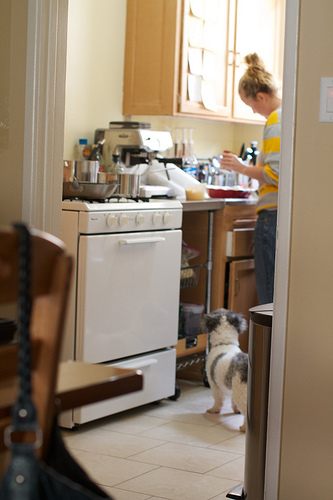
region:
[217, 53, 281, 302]
woman standing in the kitchen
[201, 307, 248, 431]
dog waiting for his food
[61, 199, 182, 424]
white stove in the corner of the kitchen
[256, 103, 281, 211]
yellow and gray top woman is wearing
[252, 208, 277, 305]
black pants woman is wearing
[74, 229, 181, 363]
front door of the white stove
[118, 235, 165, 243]
white stove door handle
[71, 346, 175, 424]
bottom drawer of the white stove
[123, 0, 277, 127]
wood cabinets on the sink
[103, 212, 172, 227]
knobs on the white stove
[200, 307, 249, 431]
A short haired white and grey dog.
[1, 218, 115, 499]
A black purse hanging on a chair.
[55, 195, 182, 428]
A white stove with black burners.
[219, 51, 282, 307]
A blonde woman in a yellow and grey shirt.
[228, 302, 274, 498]
A black and grey trashcan.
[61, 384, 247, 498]
A white tiled floor under and around a dog.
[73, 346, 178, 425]
Bottom white drawer on a stove.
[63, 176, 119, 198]
A silver frying pan on the front of the stove.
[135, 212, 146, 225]
The middle most white knob of a stove.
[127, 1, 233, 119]
Brown cabinet with sticky notes all over it.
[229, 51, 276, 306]
Woman wearing a striped shirt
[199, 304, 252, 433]
Dog standing on floor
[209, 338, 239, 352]
Collar around dog's neck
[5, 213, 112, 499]
Purse hanging on chair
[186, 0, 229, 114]
Paper hanging on cabinets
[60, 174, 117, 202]
Pan on the stove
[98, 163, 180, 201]
Pot on the stove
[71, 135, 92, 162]
Bottle next to stove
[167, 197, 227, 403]
Rack next to stove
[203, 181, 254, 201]
Platter on the counter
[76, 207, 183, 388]
that is an electric cooker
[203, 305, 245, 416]
that is a dog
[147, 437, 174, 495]
that is the kitchen floor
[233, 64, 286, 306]
that is a lady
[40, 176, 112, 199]
that is a sauce pan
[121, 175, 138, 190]
that is a metallic cup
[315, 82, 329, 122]
that is an electric switch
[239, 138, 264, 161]
these are bottles of wine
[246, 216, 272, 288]
the lady isw eaing blue jeans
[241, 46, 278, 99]
the lady has long hair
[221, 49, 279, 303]
a woman standing in the kitchen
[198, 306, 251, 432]
a small dog looking up at the woman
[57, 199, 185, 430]
a white oven in the kitchen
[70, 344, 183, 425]
a sliding storage tray underneath the oven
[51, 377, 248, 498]
a white tiled kitchen floor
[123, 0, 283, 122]
a set of wooden cabinets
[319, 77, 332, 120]
a light switch on the wall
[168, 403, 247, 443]
the shadow of the dog on the floor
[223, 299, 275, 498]
a metal trash can in the kitchen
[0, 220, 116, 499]
a black purse hanging on the back of a chair